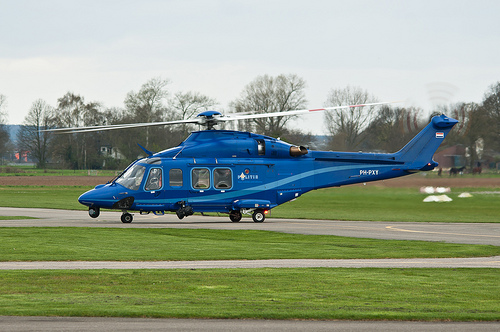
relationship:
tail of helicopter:
[394, 112, 463, 162] [30, 99, 461, 222]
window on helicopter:
[142, 168, 164, 193] [30, 99, 461, 222]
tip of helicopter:
[77, 182, 124, 210] [30, 99, 461, 222]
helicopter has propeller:
[30, 99, 461, 222] [34, 99, 408, 135]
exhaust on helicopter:
[289, 144, 309, 156] [30, 99, 461, 222]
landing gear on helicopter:
[120, 206, 134, 223] [30, 99, 461, 222]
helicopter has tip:
[30, 99, 461, 222] [77, 182, 124, 210]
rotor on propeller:
[29, 118, 204, 134] [34, 99, 408, 135]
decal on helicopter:
[237, 168, 261, 183] [30, 99, 461, 222]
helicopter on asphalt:
[30, 99, 461, 222] [3, 206, 498, 246]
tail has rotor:
[394, 112, 463, 162] [405, 77, 475, 149]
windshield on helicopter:
[111, 162, 148, 191] [30, 99, 461, 222]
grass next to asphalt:
[2, 226, 499, 263] [3, 206, 498, 246]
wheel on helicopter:
[251, 209, 267, 223] [30, 99, 461, 222]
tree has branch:
[322, 85, 382, 153] [357, 103, 377, 130]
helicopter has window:
[30, 99, 461, 222] [166, 166, 185, 190]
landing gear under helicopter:
[120, 206, 134, 223] [30, 99, 461, 222]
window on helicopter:
[191, 166, 212, 190] [30, 99, 461, 222]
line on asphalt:
[383, 223, 499, 239] [3, 206, 498, 246]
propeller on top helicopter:
[34, 99, 408, 135] [30, 99, 461, 222]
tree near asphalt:
[322, 85, 382, 153] [3, 206, 498, 246]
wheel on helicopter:
[231, 208, 244, 224] [30, 99, 461, 222]